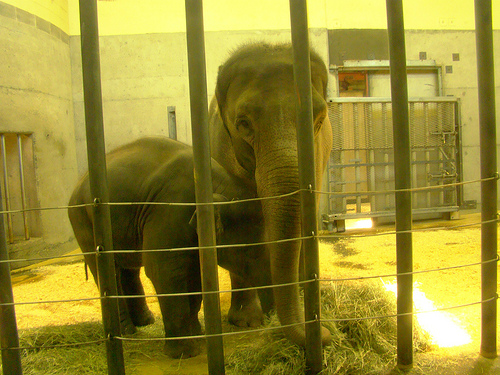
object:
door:
[328, 61, 447, 226]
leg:
[146, 244, 207, 361]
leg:
[121, 265, 156, 327]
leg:
[86, 260, 136, 337]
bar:
[288, 0, 327, 374]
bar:
[473, 0, 498, 360]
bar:
[185, 0, 225, 375]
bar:
[77, 0, 123, 373]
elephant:
[204, 42, 332, 347]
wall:
[0, 0, 79, 272]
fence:
[335, 101, 456, 210]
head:
[213, 40, 329, 200]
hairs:
[225, 36, 297, 58]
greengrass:
[226, 272, 424, 375]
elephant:
[65, 133, 293, 358]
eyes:
[236, 118, 254, 131]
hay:
[326, 292, 385, 345]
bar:
[384, 0, 413, 368]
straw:
[27, 322, 113, 371]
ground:
[15, 223, 496, 375]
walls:
[97, 32, 192, 152]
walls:
[70, 34, 91, 184]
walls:
[204, 28, 331, 114]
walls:
[402, 28, 482, 214]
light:
[388, 279, 473, 349]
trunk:
[253, 141, 334, 349]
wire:
[6, 293, 499, 351]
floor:
[8, 225, 494, 372]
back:
[91, 132, 188, 179]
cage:
[325, 67, 466, 232]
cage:
[0, 0, 499, 375]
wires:
[0, 253, 499, 311]